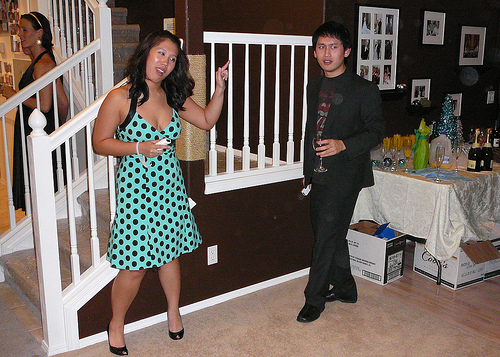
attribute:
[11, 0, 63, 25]
headband — golden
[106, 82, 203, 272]
dress — blue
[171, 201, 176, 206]
polka dot — black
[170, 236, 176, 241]
polka dot — black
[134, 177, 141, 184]
polka dot — black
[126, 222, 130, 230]
polka dot — black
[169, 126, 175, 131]
polka dot — black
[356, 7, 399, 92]
pictures — framed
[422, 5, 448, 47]
pictures — framed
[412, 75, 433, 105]
pictures — framed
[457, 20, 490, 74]
pictures — framed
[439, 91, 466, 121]
pictures — framed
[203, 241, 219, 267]
panel — white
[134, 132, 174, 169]
controller — wii, white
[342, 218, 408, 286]
cardboard box — white and black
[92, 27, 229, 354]
woman — young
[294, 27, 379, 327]
man — young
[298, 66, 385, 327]
suit — black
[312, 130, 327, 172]
glass — clear, wine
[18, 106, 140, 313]
railing — wooden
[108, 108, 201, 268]
dress — teal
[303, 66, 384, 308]
suit — black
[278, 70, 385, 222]
blazer — black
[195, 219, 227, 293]
outlet — electrical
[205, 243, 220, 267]
socket — white, electrical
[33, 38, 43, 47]
earring — sparkling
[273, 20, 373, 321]
man — young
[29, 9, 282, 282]
stairs — white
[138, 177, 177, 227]
dots — black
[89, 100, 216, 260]
dress — blue